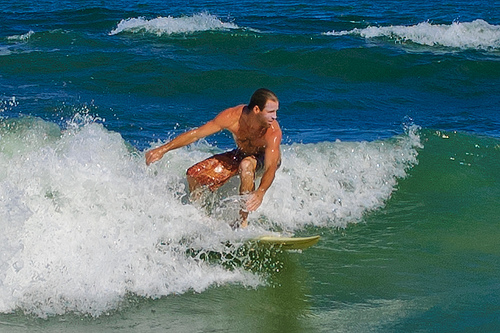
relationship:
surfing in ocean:
[128, 82, 331, 264] [317, 10, 495, 325]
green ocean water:
[381, 214, 489, 320] [360, 102, 496, 241]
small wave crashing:
[122, 9, 246, 52] [129, 12, 295, 61]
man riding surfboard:
[150, 85, 287, 230] [187, 217, 342, 255]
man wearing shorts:
[150, 85, 287, 230] [186, 147, 265, 188]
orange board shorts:
[201, 162, 232, 177] [186, 147, 265, 188]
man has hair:
[150, 85, 287, 230] [250, 84, 279, 108]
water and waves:
[360, 102, 496, 241] [14, 117, 143, 284]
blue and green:
[328, 88, 377, 126] [381, 214, 489, 320]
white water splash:
[55, 151, 121, 219] [31, 102, 117, 229]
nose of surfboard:
[290, 228, 321, 254] [187, 217, 342, 255]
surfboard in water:
[187, 217, 342, 255] [360, 102, 496, 241]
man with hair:
[150, 85, 287, 230] [233, 128, 268, 156]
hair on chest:
[233, 128, 268, 156] [229, 111, 269, 158]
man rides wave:
[150, 85, 287, 230] [273, 128, 458, 225]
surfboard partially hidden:
[187, 217, 342, 255] [178, 217, 273, 262]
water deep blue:
[38, 40, 150, 105] [328, 88, 377, 126]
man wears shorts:
[150, 85, 287, 230] [186, 147, 265, 188]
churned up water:
[297, 132, 376, 214] [360, 102, 496, 241]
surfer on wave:
[128, 82, 331, 264] [273, 128, 458, 225]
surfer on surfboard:
[150, 85, 287, 230] [187, 217, 342, 255]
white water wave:
[55, 151, 121, 219] [273, 128, 458, 225]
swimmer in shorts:
[150, 85, 287, 230] [186, 147, 265, 188]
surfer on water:
[128, 82, 331, 264] [360, 102, 496, 241]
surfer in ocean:
[150, 85, 287, 230] [317, 10, 495, 325]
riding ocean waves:
[58, 122, 387, 270] [59, 139, 485, 194]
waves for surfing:
[59, 139, 485, 194] [128, 82, 331, 264]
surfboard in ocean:
[187, 217, 342, 255] [317, 10, 495, 325]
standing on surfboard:
[191, 55, 297, 257] [187, 217, 342, 255]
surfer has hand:
[150, 85, 287, 230] [141, 130, 190, 167]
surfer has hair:
[128, 82, 331, 264] [250, 84, 279, 108]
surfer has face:
[128, 82, 331, 264] [262, 100, 282, 129]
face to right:
[262, 100, 282, 129] [242, 78, 292, 136]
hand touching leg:
[247, 184, 268, 215] [238, 159, 252, 236]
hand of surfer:
[247, 184, 268, 215] [128, 82, 331, 264]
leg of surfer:
[238, 159, 252, 236] [128, 82, 331, 264]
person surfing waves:
[150, 85, 287, 230] [59, 139, 485, 194]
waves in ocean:
[59, 139, 485, 194] [317, 10, 495, 325]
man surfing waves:
[150, 85, 287, 230] [59, 139, 485, 194]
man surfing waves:
[150, 85, 287, 230] [14, 117, 143, 284]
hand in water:
[141, 130, 190, 167] [360, 102, 496, 241]